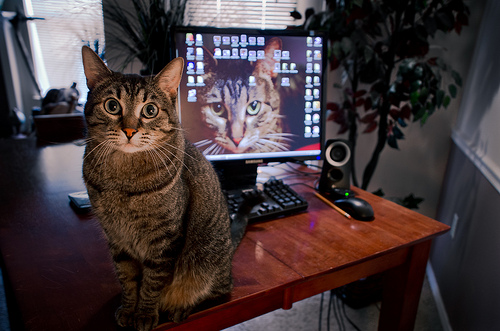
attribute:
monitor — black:
[182, 22, 335, 162]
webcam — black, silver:
[319, 136, 359, 196]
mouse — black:
[336, 191, 376, 220]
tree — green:
[289, 0, 481, 310]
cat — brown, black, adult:
[77, 40, 242, 329]